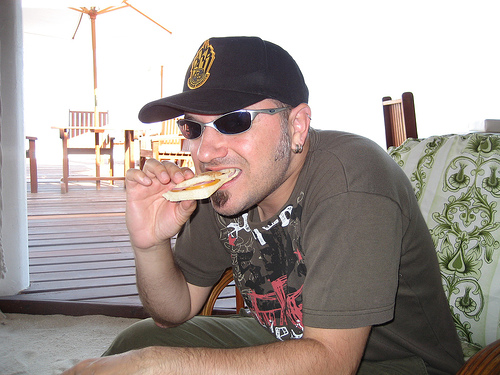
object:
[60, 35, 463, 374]
man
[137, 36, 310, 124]
cap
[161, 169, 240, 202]
pizza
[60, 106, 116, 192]
chair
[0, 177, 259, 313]
deck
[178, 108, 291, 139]
sunglasses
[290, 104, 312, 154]
ear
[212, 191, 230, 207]
soul patch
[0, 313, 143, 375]
shag carpet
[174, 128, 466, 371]
shirt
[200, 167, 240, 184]
mouth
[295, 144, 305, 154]
earring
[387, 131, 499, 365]
blanket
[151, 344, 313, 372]
arm hair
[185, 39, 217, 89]
logo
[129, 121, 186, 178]
bench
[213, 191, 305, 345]
logo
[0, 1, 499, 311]
background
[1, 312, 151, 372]
sand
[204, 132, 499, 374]
chair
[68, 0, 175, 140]
table umbrella